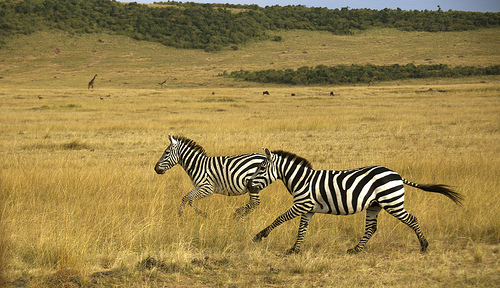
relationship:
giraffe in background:
[86, 70, 98, 92] [4, 29, 495, 93]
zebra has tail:
[247, 148, 464, 262] [403, 176, 463, 207]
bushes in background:
[1, 3, 500, 57] [4, 29, 495, 93]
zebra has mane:
[247, 148, 464, 262] [270, 148, 313, 168]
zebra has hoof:
[247, 148, 464, 262] [252, 233, 263, 243]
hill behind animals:
[1, 1, 500, 47] [263, 90, 338, 106]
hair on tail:
[417, 182, 460, 203] [403, 176, 463, 207]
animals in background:
[263, 90, 338, 106] [4, 29, 495, 93]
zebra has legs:
[247, 148, 464, 262] [259, 212, 429, 253]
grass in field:
[0, 86, 495, 286] [7, 32, 498, 283]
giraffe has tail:
[86, 70, 98, 92] [86, 83, 88, 86]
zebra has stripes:
[247, 148, 464, 262] [300, 170, 378, 209]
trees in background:
[1, 3, 500, 57] [4, 29, 495, 93]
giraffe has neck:
[86, 70, 98, 92] [93, 78, 97, 81]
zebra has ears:
[247, 148, 464, 262] [263, 148, 273, 160]